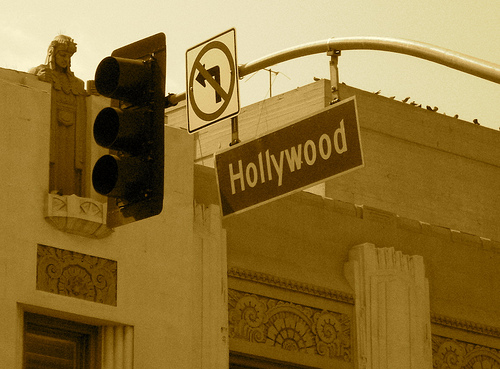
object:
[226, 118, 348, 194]
hollywood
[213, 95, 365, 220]
sign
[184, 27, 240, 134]
no-left-turn sign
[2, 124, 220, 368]
building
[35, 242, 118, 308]
details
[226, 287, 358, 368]
details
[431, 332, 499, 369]
details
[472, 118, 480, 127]
bird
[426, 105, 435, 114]
bird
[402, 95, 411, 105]
bird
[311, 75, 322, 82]
bird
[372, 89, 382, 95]
bird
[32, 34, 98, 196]
statue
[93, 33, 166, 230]
traffic signal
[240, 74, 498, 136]
roof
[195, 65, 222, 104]
arrow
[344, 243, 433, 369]
pillar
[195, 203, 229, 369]
pillar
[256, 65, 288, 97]
antenna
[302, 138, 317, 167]
letter o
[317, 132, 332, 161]
letter o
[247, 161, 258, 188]
letter o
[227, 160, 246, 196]
letter h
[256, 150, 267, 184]
letter l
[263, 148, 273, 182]
letter l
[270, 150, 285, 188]
y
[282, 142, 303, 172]
w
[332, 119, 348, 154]
d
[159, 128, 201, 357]
wall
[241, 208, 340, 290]
wall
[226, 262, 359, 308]
design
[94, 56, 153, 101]
light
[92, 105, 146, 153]
light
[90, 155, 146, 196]
light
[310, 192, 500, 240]
design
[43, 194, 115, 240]
design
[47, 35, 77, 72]
head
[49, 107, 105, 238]
drain